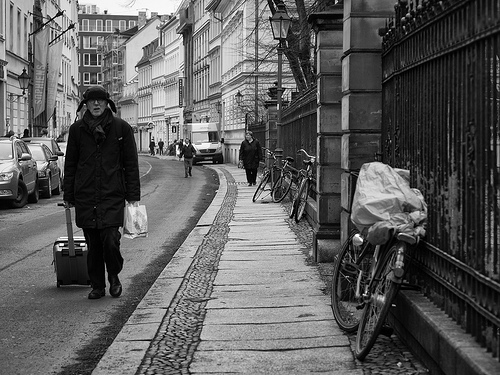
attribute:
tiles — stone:
[225, 257, 303, 351]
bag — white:
[119, 206, 150, 243]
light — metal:
[269, 2, 293, 194]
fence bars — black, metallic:
[363, 11, 494, 156]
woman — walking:
[235, 129, 261, 188]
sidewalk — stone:
[136, 164, 356, 374]